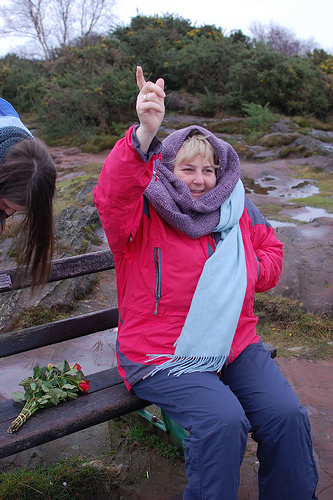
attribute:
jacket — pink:
[92, 123, 292, 383]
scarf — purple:
[221, 155, 246, 184]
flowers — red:
[65, 360, 89, 400]